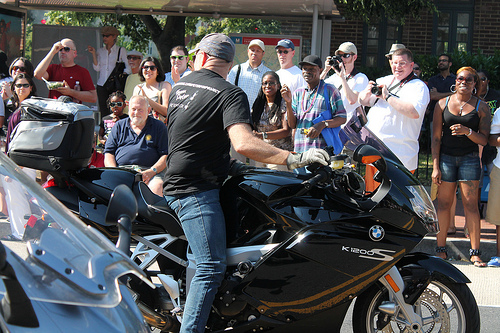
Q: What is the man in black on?
A: A motorcycle.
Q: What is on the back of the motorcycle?
A: A bag.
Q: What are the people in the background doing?
A: Watching.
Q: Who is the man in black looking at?
A: Someone behind him.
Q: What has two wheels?
A: The motorcycle.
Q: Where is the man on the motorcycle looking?
A: At the crowd.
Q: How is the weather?
A: Sunny.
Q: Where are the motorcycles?
A: On the road.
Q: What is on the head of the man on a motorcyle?
A: A cap.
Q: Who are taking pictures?
A: The people with cameras.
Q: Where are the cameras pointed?
A: On the road.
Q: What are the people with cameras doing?
A: Taking pictures.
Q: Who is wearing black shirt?
A: The man.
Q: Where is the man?
A: Motocycle.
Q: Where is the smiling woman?
A: Side of road.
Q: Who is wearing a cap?
A: The man.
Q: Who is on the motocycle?
A: The man.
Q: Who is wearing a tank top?
A: The woman.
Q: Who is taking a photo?
A: The man.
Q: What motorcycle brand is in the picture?
A: BMW.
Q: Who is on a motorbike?
A: One man.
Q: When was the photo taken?
A: Daytime.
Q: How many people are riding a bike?
A: One.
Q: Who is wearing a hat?
A: Man on motorcycle.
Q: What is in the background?
A: A tree.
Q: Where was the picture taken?
A: At a parade.